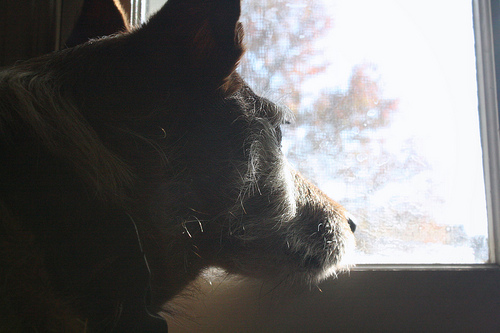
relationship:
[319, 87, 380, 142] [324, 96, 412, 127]
leaf on a stem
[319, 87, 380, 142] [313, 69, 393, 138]
leaf on stem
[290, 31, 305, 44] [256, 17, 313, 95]
leaf on stem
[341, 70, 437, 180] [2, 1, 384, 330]
window in front of dog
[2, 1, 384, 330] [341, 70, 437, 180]
dog in front of window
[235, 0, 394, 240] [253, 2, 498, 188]
tree behind window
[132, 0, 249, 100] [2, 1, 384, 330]
ear of dog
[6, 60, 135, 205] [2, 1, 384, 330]
white hair on dog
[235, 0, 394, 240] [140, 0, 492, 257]
tree outside window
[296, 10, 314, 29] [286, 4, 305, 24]
leaf on stem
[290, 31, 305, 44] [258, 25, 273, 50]
leaf on stem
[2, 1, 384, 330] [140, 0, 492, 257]
dog looking out window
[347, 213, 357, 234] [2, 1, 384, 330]
nose on dog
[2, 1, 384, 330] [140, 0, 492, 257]
dog looking at window